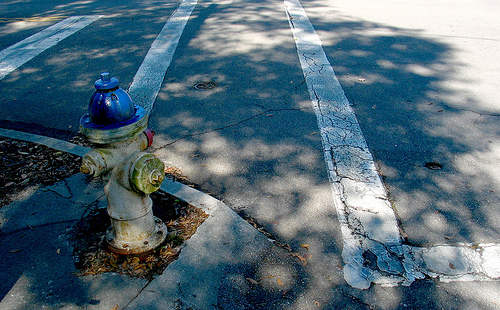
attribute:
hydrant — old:
[78, 71, 168, 256]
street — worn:
[2, 1, 499, 282]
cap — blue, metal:
[79, 74, 145, 130]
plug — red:
[144, 127, 154, 149]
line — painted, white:
[284, 1, 401, 289]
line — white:
[128, 1, 198, 112]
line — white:
[1, 14, 102, 79]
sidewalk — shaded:
[1, 216, 247, 310]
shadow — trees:
[317, 21, 492, 110]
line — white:
[349, 244, 498, 286]